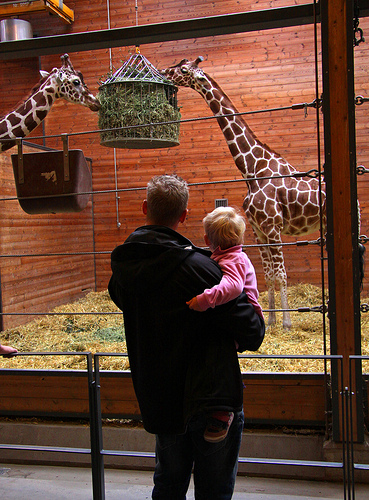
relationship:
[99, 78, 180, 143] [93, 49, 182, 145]
grass in cage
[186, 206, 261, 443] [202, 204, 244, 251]
child has hair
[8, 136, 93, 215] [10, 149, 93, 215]
food container hanging off bucket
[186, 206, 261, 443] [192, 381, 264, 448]
child has shoes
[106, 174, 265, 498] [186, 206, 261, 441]
man holding child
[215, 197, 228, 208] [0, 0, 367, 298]
vent in wall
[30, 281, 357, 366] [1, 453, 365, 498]
straw on floor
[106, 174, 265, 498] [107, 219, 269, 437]
man wearing jacket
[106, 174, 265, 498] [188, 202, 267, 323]
man holding child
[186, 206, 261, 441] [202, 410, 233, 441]
child wearing shoe